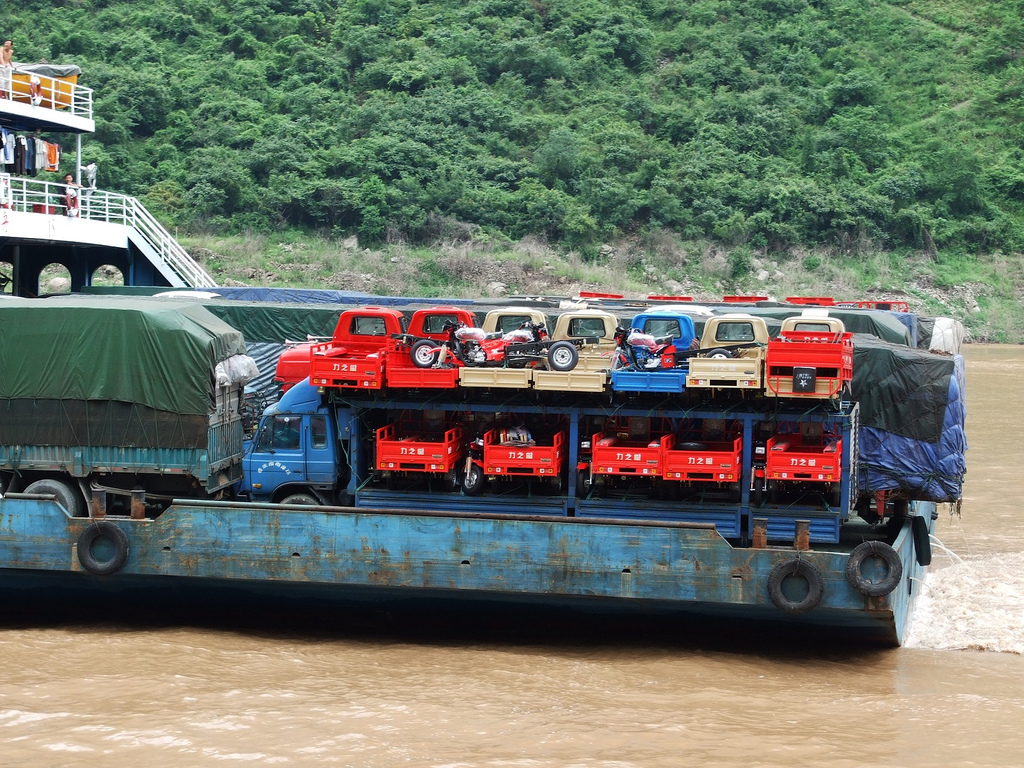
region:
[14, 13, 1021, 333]
The forest of trees in the background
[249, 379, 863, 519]
The blue truck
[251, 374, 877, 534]
A blue truck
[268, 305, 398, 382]
A red truck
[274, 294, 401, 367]
The red truck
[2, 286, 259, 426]
A green tarp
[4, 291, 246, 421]
The green tarp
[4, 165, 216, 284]
The bottom balcony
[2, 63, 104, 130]
The top balcony on the boat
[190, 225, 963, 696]
trucks are on the boat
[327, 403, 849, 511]
the trucks are red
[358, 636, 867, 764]
the water is brown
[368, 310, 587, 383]
a bike is on the trucks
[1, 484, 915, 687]
the boat is blue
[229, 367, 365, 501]
the truck holding the other vehicles is blue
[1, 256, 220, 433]
the tarp is green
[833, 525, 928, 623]
the wheel is black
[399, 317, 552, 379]
the bike is red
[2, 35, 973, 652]
large blue barge floating down brown river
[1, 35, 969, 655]
dirty barge filled with red and beige pickup trucks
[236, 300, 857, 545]
blue truck holding several smaller trucks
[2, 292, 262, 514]
light blue vehicle covered with green tarp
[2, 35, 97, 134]
person standing on balcony with white rail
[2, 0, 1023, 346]
large hill full of green trees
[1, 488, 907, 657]
wall with three black tires hanging on it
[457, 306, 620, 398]
two beige trucks parked next to each other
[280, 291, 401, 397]
Red truck on the boat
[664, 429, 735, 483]
Red truck on the boat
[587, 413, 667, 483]
Red truck on the boat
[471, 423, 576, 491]
Red truck on the boat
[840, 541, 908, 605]
tire hanging from a boat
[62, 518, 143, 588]
tire hanging from a boat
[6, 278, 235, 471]
green trap on the truck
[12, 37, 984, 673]
ferry in the water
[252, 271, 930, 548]
truck on the ferry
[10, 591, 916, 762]
the water is brown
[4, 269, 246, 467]
tarp on a truck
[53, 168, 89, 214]
person on the ferry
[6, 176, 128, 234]
railing on the ferry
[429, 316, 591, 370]
bike on a truck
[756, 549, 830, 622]
tire on the side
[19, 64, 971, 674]
a large cargo ship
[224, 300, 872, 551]
truck on a ferry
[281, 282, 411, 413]
red truck on a truck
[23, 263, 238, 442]
green tarp on ferry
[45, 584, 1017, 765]
a body of water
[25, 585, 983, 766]
the water is brown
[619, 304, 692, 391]
blue truck on the truck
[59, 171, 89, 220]
person on the ferry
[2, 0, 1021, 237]
The trees in the background are green in color.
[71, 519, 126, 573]
The tire on the left is round in shape.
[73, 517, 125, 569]
The tire on the left is black in color.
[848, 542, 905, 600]
The tire on the right is black in color.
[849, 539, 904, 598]
The tire on the right is round in shape.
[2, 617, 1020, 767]
The water in the forefront is brown in color.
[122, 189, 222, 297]
The railing on the boat is white in color.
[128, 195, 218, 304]
The railing on the boat is made from steel.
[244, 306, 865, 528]
The truck on the boat is blue in color.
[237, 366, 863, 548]
large blue truck on barge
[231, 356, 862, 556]
truck on barge is blue